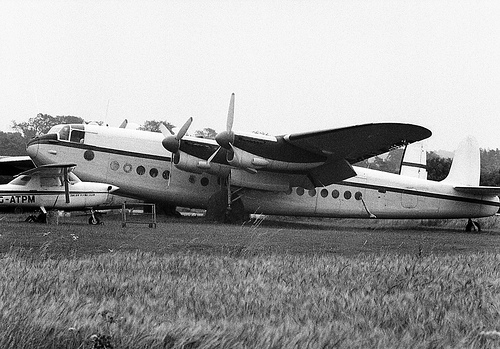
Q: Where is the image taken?
A: Runway.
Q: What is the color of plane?
A: White.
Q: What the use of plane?
A: Travel.